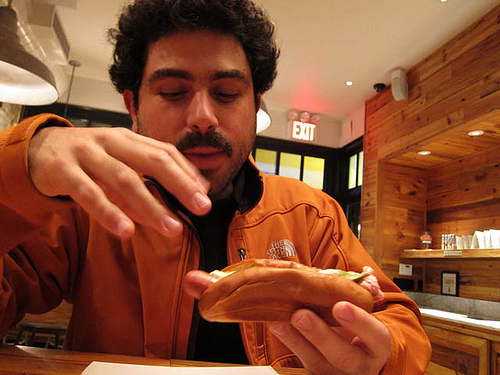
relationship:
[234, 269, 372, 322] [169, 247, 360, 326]
bun of dog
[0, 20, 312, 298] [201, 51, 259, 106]
man has eye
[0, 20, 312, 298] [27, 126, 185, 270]
man has hand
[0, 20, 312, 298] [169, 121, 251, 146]
man has mustached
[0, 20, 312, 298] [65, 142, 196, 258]
man has finger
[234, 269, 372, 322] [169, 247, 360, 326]
bun on dog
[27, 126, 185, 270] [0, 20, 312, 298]
hand of man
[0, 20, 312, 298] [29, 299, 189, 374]
man beside table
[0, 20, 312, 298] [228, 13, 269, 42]
man has hair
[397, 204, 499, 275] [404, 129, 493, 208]
shelf against wall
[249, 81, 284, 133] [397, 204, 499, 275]
light above shelf